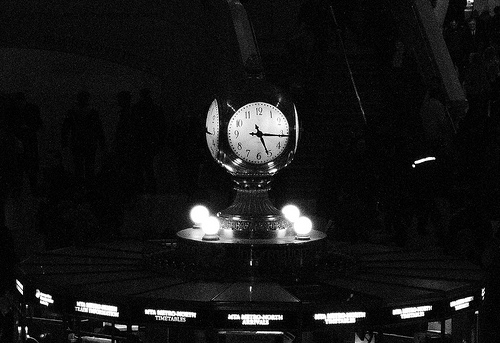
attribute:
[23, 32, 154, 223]
wall — brick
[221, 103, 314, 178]
clock — four sides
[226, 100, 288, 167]
clock — round, white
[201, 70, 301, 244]
clock — round, four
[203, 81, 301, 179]
clock — black , white 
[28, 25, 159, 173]
dark — black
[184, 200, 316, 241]
lights — 4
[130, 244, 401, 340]
black table — large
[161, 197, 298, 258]
lights — bright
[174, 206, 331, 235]
bulbs — turned on